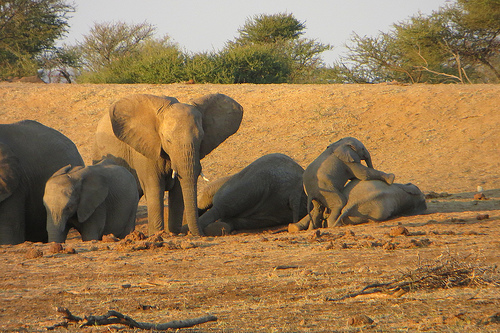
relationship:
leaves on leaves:
[312, 45, 333, 51] [0, 0, 500, 84]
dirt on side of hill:
[250, 114, 498, 138] [387, 105, 457, 136]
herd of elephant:
[1, 90, 430, 247] [343, 177, 430, 224]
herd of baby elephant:
[1, 90, 430, 247] [43, 164, 139, 244]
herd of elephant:
[1, 90, 430, 247] [198, 150, 309, 227]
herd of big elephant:
[1, 90, 430, 247] [93, 92, 243, 236]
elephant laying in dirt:
[181, 152, 311, 238] [10, 244, 496, 324]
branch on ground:
[46, 308, 223, 329] [1, 230, 498, 329]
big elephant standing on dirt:
[93, 92, 243, 236] [1, 79, 499, 330]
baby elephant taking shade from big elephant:
[43, 155, 145, 245] [93, 92, 243, 236]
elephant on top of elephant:
[293, 132, 398, 234] [334, 174, 433, 224]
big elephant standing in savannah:
[93, 92, 243, 236] [50, 40, 492, 330]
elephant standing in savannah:
[293, 132, 398, 234] [22, 23, 494, 320]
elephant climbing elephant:
[283, 115, 435, 232] [330, 157, 437, 224]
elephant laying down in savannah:
[286, 175, 425, 232] [10, 55, 497, 329]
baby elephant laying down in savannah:
[43, 164, 139, 244] [10, 55, 497, 329]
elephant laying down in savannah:
[181, 152, 311, 238] [10, 55, 497, 329]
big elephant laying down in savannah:
[93, 92, 243, 236] [10, 55, 497, 329]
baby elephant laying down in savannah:
[43, 164, 139, 244] [1, 80, 497, 331]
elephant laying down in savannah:
[286, 175, 425, 232] [1, 80, 497, 331]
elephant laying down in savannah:
[181, 152, 311, 238] [1, 80, 497, 331]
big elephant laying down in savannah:
[93, 92, 243, 236] [1, 80, 497, 331]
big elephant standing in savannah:
[93, 92, 243, 236] [3, 14, 482, 328]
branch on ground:
[44, 308, 221, 329] [20, 253, 463, 326]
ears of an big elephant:
[113, 91, 242, 152] [93, 92, 243, 236]